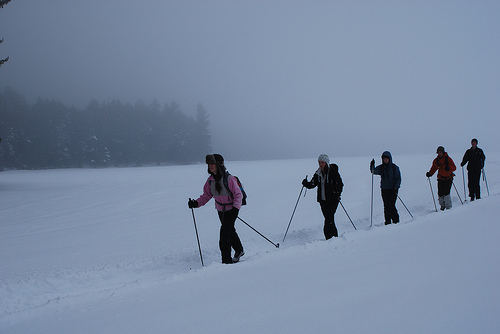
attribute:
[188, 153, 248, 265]
skier — cross country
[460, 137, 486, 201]
skier — end of line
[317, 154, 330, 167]
hat — white, knit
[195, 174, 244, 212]
jacket — pink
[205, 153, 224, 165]
hat — black, warm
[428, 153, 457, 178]
jacket — red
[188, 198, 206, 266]
pole — cross country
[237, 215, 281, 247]
pole — cross country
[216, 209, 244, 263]
pants — dark, black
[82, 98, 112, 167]
tree — thick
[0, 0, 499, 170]
fog — dark, dismal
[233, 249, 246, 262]
boot — cross country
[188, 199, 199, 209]
glove — black